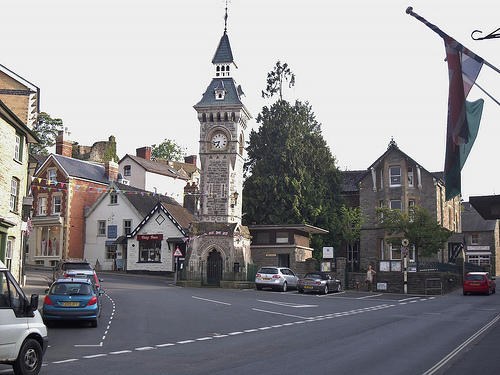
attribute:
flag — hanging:
[402, 3, 497, 143]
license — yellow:
[58, 297, 84, 308]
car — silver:
[296, 273, 348, 299]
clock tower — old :
[185, 22, 261, 289]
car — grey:
[297, 274, 344, 295]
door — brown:
[200, 242, 224, 298]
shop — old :
[108, 187, 206, 287]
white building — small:
[79, 177, 189, 275]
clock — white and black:
[209, 127, 229, 154]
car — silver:
[253, 264, 299, 292]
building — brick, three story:
[29, 162, 96, 264]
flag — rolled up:
[416, 2, 499, 173]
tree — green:
[245, 61, 354, 274]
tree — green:
[335, 205, 358, 278]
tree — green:
[377, 205, 448, 270]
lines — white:
[44, 315, 384, 369]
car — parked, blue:
[40, 277, 105, 327]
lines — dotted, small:
[192, 314, 299, 337]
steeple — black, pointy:
[204, 2, 284, 149]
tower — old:
[185, 22, 255, 281]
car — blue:
[42, 271, 107, 332]